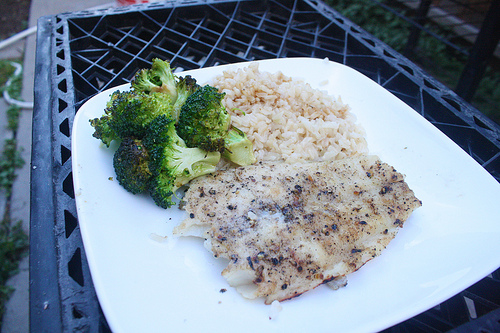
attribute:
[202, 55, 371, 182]
rice — brown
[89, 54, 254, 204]
broccoli — cooked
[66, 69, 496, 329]
plate — white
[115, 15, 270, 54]
rack — black, metal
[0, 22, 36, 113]
hose — grey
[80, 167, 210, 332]
plate — white, square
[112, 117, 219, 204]
broccoli piece — cooked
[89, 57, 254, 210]
brocolli — green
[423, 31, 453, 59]
bushes — small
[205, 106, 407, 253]
fish — cooked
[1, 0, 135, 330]
sidewalk — grey 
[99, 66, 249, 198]
broccoli — cooked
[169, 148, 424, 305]
fish — peppered, cooked